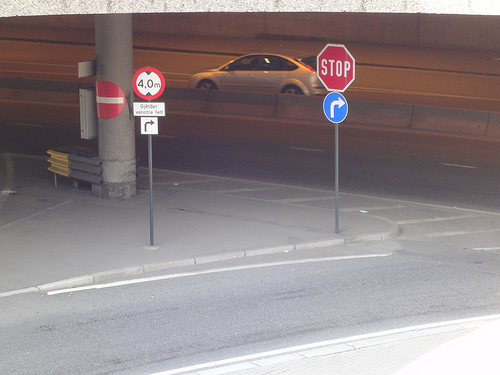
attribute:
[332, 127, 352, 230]
post — metal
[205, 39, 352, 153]
car — silver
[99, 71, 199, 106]
sign — white, red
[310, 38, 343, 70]
sign — red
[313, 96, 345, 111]
sign — blue, white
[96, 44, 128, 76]
pillar — grey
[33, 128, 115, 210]
barricade — grey, yellow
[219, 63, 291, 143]
wall — grey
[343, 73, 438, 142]
overpass — grey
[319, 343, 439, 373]
sidewalk — grey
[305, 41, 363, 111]
sign — red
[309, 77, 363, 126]
sign — blue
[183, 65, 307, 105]
car — silver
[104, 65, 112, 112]
sign — red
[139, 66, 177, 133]
sign — red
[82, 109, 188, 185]
pole — grey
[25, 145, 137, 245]
divider — metal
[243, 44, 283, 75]
glass — clear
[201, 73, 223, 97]
tire — black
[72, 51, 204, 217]
pole — tall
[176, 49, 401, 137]
car — grey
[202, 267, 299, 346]
street — grey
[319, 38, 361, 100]
sign — white, red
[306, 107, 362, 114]
sign — blue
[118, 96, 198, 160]
sign — black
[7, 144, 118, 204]
barrier — ggrey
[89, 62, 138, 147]
sign — red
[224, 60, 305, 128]
car — white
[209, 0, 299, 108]
car — white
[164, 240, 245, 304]
lines — white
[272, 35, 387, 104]
sign — red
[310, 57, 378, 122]
sign — white, blue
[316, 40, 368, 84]
sign — red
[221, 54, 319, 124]
car — silver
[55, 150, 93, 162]
rail — silver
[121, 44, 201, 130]
sign — red, white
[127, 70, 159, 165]
sign — white, black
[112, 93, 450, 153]
arrows — black, white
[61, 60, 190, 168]
sign — white, red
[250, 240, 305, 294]
lines — white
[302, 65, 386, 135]
sign — white, blue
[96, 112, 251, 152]
sign — black, white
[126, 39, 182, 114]
sign — white, red, black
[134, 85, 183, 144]
sign — white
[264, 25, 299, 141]
car — tan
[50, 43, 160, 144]
sign — red, white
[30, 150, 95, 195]
rail — grey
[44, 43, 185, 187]
pillar — grey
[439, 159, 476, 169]
line — white, painted